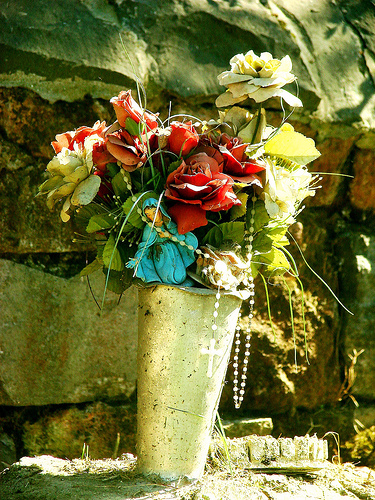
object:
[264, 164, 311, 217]
flower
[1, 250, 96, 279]
crack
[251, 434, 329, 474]
dirt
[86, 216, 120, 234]
leaf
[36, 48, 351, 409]
group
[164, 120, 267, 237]
flower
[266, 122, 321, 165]
petals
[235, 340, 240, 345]
bead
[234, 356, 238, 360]
bead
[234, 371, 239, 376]
bead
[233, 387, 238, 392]
bead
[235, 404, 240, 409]
bead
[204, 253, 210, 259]
beads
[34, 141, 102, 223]
flower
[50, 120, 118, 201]
flower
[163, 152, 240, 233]
opened red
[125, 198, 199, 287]
figurine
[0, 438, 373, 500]
ground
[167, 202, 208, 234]
petal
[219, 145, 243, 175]
petal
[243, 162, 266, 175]
petal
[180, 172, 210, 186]
petal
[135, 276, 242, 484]
flower vase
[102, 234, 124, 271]
green leaf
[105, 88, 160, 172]
flower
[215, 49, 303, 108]
flower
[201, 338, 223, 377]
cross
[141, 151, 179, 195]
hoops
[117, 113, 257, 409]
rosary